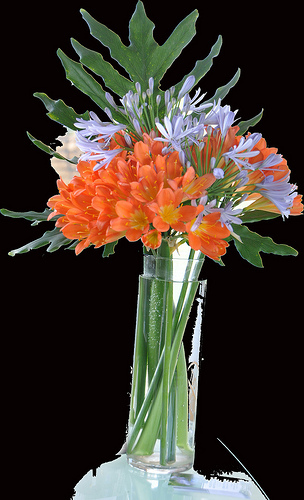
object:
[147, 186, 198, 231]
flowers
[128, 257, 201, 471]
vase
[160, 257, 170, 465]
stems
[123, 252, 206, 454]
stems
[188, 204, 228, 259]
leaves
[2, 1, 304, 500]
background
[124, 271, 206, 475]
water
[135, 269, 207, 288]
line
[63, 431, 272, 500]
material